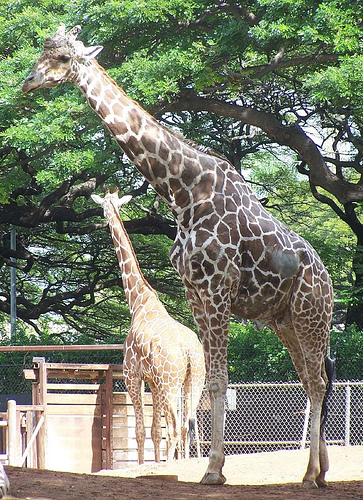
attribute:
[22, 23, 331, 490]
giraffe — younger, older, small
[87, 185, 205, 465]
giraffe — small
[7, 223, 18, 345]
pole — silver, metal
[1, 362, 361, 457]
fence — chain link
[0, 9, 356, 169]
trees — lush, green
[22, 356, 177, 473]
slats — wooden, horizontal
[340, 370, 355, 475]
rails — silver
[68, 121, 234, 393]
giraffe — brown, spotted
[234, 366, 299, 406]
fence — short, chain link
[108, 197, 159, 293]
mane — brown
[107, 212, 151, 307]
neck — long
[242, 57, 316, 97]
branches — leafy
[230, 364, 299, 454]
fence — chain link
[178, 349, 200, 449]
tail — long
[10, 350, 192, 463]
structure — wooden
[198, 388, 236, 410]
sticker — white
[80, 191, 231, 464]
giraffee — small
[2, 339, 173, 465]
structure — low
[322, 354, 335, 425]
hair — dark, long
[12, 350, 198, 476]
fence — short, wooden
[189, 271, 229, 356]
spots — brown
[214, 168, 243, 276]
spots — brown 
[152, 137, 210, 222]
fur — beige 